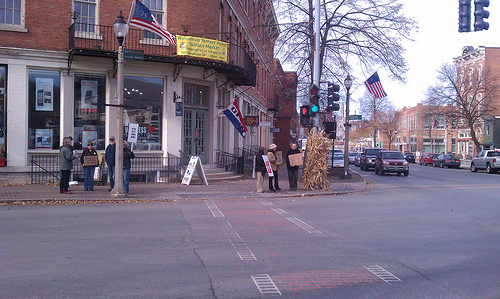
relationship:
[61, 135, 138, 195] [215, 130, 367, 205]
people near a corner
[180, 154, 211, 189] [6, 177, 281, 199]
sign on sidewalk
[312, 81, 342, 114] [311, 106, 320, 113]
traffic light set to green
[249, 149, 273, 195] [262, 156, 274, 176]
person wears white and red sign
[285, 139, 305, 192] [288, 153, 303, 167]
person holds a sign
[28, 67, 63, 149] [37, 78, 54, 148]
window with posters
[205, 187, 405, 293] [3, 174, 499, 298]
lines on street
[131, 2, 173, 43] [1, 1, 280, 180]
flag in front of a building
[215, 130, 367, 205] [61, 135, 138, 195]
corner with people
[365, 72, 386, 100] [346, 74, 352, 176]
flag on a lamppost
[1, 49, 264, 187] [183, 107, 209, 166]
storefront has grey doors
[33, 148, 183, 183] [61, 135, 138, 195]
railing behind people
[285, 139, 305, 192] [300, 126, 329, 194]
person next to corn stalks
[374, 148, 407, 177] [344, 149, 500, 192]
car on street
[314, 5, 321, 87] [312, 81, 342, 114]
pole with a traffic light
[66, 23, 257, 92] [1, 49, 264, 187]
railing over storefront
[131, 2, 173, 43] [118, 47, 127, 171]
flag waves from a lamppost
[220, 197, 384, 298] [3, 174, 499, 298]
crosswalk on street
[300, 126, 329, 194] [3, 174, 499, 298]
corn stalks next to street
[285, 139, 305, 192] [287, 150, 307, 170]
person holding sign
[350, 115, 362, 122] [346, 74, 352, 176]
street sign on a lamppost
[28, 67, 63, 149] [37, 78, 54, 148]
window has posters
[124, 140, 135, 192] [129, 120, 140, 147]
person holds a picket sign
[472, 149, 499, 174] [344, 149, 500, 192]
car in street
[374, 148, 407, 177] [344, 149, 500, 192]
car in street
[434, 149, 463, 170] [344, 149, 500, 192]
car on street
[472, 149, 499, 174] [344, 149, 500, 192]
car on street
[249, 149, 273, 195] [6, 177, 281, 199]
person on sidewalk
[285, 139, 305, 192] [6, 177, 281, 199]
person on sidewalk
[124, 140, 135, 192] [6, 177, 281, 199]
person on sidewalk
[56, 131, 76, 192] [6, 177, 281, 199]
person on sidewalk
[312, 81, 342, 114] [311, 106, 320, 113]
traffic light lit to green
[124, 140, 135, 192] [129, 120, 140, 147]
person with picket sign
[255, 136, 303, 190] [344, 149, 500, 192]
people on side street